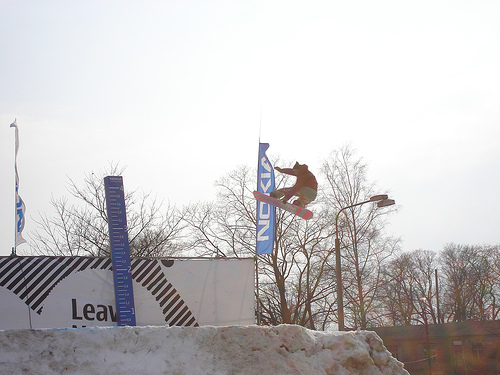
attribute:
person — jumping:
[287, 166, 320, 203]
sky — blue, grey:
[42, 18, 91, 31]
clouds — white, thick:
[279, 42, 298, 61]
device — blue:
[120, 297, 135, 320]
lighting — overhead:
[6, 110, 20, 171]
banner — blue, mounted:
[254, 233, 269, 250]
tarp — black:
[36, 260, 69, 277]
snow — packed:
[152, 341, 190, 349]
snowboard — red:
[231, 199, 309, 218]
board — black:
[15, 244, 74, 324]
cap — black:
[292, 161, 302, 167]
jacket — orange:
[305, 176, 320, 183]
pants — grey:
[304, 197, 312, 201]